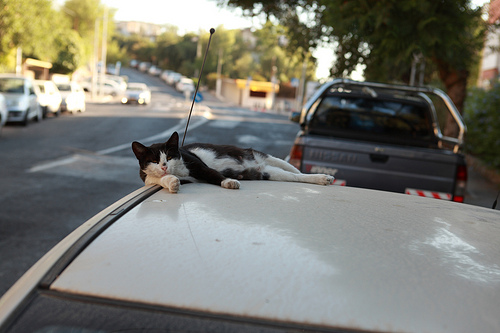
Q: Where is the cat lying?
A: On a car.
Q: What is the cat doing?
A: Sleeping.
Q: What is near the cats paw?
A: Antenna.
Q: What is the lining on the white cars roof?
A: Rubber strips.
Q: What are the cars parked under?
A: Shade.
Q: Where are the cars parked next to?
A: Sidewalk.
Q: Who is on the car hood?
A: Cat.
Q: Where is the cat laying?
A: On the hood.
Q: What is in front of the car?
A: Truck.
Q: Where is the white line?
A: On the road.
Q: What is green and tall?
A: Trees.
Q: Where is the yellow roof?
A: On the building.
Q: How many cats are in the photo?
A: One.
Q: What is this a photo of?
A: A cat on a car.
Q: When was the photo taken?
A: Daytime.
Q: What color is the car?
A: White.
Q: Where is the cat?
A: On top of the car.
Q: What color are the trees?
A: Green.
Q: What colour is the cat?
A: Black and white.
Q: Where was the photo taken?
A: On the street.